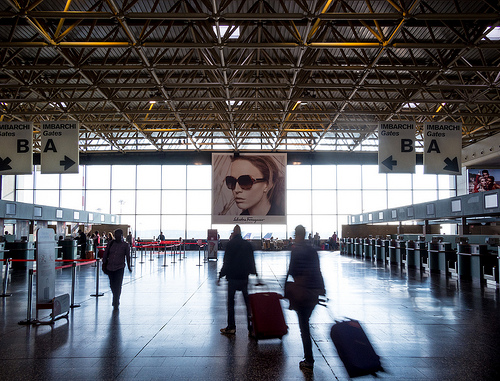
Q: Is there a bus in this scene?
A: No, there are no buses.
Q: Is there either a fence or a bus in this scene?
A: No, there are no buses or fences.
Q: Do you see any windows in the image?
A: Yes, there are windows.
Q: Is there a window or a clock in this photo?
A: Yes, there are windows.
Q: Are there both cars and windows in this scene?
A: No, there are windows but no cars.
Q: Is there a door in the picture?
A: No, there are no doors.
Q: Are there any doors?
A: No, there are no doors.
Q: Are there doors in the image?
A: No, there are no doors.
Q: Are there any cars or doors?
A: No, there are no doors or cars.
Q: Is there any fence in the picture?
A: No, there are no fences.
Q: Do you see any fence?
A: No, there are no fences.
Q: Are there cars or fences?
A: No, there are no fences or cars.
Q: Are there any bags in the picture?
A: Yes, there is a bag.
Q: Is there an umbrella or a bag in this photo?
A: Yes, there is a bag.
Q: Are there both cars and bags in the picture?
A: No, there is a bag but no cars.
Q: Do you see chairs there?
A: No, there are no chairs.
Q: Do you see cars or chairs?
A: No, there are no chairs or cars.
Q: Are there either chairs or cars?
A: No, there are no chairs or cars.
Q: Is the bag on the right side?
A: Yes, the bag is on the right of the image.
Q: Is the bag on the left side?
A: No, the bag is on the right of the image.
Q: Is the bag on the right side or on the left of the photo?
A: The bag is on the right of the image.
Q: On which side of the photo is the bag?
A: The bag is on the right of the image.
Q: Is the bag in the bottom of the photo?
A: Yes, the bag is in the bottom of the image.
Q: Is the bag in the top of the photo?
A: No, the bag is in the bottom of the image.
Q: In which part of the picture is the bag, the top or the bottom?
A: The bag is in the bottom of the image.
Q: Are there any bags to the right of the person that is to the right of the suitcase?
A: Yes, there is a bag to the right of the person.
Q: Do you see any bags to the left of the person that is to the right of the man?
A: No, the bag is to the right of the person.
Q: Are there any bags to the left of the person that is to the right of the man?
A: No, the bag is to the right of the person.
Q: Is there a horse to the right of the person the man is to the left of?
A: No, there is a bag to the right of the person.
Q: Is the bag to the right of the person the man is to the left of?
A: Yes, the bag is to the right of the person.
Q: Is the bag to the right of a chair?
A: No, the bag is to the right of the person.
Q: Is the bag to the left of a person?
A: No, the bag is to the right of a person.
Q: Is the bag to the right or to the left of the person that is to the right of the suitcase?
A: The bag is to the right of the person.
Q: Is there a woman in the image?
A: Yes, there is a woman.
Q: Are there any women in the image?
A: Yes, there is a woman.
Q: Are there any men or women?
A: Yes, there is a woman.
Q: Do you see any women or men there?
A: Yes, there is a woman.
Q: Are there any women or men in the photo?
A: Yes, there is a woman.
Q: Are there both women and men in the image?
A: Yes, there are both a woman and a man.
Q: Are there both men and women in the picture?
A: Yes, there are both a woman and a man.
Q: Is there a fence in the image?
A: No, there are no fences.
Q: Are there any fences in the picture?
A: No, there are no fences.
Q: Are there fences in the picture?
A: No, there are no fences.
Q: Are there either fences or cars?
A: No, there are no fences or cars.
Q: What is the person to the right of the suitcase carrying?
A: The person is carrying a bag.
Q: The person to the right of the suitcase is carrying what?
A: The person is carrying a bag.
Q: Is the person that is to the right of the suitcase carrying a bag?
A: Yes, the person is carrying a bag.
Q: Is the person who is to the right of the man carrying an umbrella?
A: No, the person is carrying a bag.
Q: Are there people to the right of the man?
A: Yes, there is a person to the right of the man.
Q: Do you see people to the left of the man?
A: No, the person is to the right of the man.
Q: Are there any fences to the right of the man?
A: No, there is a person to the right of the man.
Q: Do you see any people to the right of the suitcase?
A: Yes, there is a person to the right of the suitcase.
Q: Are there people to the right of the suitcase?
A: Yes, there is a person to the right of the suitcase.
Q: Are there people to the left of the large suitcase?
A: No, the person is to the right of the suitcase.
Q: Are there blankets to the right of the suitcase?
A: No, there is a person to the right of the suitcase.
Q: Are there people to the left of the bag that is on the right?
A: Yes, there is a person to the left of the bag.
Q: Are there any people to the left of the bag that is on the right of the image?
A: Yes, there is a person to the left of the bag.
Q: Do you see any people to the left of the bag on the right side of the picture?
A: Yes, there is a person to the left of the bag.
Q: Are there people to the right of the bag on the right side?
A: No, the person is to the left of the bag.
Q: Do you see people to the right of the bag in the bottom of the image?
A: No, the person is to the left of the bag.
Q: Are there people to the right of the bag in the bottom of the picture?
A: No, the person is to the left of the bag.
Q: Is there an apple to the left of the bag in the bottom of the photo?
A: No, there is a person to the left of the bag.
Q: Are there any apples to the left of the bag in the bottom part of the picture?
A: No, there is a person to the left of the bag.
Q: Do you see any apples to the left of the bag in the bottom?
A: No, there is a person to the left of the bag.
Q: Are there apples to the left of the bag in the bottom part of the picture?
A: No, there is a person to the left of the bag.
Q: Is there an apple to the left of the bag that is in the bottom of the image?
A: No, there is a person to the left of the bag.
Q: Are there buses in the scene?
A: No, there are no buses.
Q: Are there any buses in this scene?
A: No, there are no buses.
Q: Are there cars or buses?
A: No, there are no buses or cars.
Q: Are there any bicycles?
A: No, there are no bicycles.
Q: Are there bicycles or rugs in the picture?
A: No, there are no bicycles or rugs.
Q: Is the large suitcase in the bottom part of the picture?
A: Yes, the suitcase is in the bottom of the image.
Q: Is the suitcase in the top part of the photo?
A: No, the suitcase is in the bottom of the image.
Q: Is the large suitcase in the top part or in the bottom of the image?
A: The suitcase is in the bottom of the image.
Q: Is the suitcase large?
A: Yes, the suitcase is large.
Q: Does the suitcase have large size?
A: Yes, the suitcase is large.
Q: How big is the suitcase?
A: The suitcase is large.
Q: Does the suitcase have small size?
A: No, the suitcase is large.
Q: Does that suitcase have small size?
A: No, the suitcase is large.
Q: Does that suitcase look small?
A: No, the suitcase is large.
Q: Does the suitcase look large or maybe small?
A: The suitcase is large.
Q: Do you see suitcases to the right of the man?
A: Yes, there is a suitcase to the right of the man.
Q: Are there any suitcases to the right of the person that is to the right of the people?
A: Yes, there is a suitcase to the right of the man.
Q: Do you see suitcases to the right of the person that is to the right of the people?
A: Yes, there is a suitcase to the right of the man.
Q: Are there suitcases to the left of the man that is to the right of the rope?
A: No, the suitcase is to the right of the man.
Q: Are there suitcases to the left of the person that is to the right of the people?
A: No, the suitcase is to the right of the man.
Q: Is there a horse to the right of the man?
A: No, there is a suitcase to the right of the man.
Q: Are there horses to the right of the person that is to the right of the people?
A: No, there is a suitcase to the right of the man.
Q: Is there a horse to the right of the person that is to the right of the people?
A: No, there is a suitcase to the right of the man.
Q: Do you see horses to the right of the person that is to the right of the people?
A: No, there is a suitcase to the right of the man.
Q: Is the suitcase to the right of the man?
A: Yes, the suitcase is to the right of the man.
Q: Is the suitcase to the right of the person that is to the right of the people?
A: Yes, the suitcase is to the right of the man.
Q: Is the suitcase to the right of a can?
A: No, the suitcase is to the right of the man.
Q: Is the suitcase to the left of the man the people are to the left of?
A: No, the suitcase is to the right of the man.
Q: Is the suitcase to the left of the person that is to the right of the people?
A: No, the suitcase is to the right of the man.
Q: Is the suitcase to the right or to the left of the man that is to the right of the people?
A: The suitcase is to the right of the man.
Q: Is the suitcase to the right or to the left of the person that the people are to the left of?
A: The suitcase is to the right of the man.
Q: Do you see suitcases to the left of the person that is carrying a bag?
A: Yes, there is a suitcase to the left of the person.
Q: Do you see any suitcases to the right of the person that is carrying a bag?
A: No, the suitcase is to the left of the person.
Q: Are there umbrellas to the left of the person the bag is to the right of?
A: No, there is a suitcase to the left of the person.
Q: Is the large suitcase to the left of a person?
A: Yes, the suitcase is to the left of a person.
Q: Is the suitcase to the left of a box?
A: No, the suitcase is to the left of a person.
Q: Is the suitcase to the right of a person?
A: No, the suitcase is to the left of a person.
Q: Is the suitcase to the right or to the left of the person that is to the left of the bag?
A: The suitcase is to the left of the person.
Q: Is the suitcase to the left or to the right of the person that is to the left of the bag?
A: The suitcase is to the left of the person.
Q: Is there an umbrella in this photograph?
A: No, there are no umbrellas.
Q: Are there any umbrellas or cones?
A: No, there are no umbrellas or cones.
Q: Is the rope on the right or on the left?
A: The rope is on the left of the image.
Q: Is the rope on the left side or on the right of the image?
A: The rope is on the left of the image.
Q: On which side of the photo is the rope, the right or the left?
A: The rope is on the left of the image.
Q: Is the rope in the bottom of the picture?
A: Yes, the rope is in the bottom of the image.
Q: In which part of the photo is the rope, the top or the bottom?
A: The rope is in the bottom of the image.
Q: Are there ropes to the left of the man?
A: Yes, there is a rope to the left of the man.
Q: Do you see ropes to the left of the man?
A: Yes, there is a rope to the left of the man.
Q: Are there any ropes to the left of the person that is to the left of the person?
A: Yes, there is a rope to the left of the man.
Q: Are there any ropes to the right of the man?
A: No, the rope is to the left of the man.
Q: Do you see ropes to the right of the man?
A: No, the rope is to the left of the man.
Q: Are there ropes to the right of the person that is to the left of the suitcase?
A: No, the rope is to the left of the man.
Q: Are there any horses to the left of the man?
A: No, there is a rope to the left of the man.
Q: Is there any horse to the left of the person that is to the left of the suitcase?
A: No, there is a rope to the left of the man.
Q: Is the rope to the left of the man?
A: Yes, the rope is to the left of the man.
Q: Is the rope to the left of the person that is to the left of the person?
A: Yes, the rope is to the left of the man.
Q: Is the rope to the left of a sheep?
A: No, the rope is to the left of the man.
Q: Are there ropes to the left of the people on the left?
A: Yes, there is a rope to the left of the people.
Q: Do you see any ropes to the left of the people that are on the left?
A: Yes, there is a rope to the left of the people.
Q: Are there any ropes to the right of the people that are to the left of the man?
A: No, the rope is to the left of the people.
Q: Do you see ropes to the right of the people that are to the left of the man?
A: No, the rope is to the left of the people.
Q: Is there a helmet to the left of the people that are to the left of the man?
A: No, there is a rope to the left of the people.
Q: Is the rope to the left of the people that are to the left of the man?
A: Yes, the rope is to the left of the people.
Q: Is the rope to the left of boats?
A: No, the rope is to the left of the people.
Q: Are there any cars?
A: No, there are no cars.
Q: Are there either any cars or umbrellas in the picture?
A: No, there are no cars or umbrellas.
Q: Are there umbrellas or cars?
A: No, there are no cars or umbrellas.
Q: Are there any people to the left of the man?
A: Yes, there are people to the left of the man.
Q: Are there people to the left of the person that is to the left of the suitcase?
A: Yes, there are people to the left of the man.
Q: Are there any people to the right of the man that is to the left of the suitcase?
A: No, the people are to the left of the man.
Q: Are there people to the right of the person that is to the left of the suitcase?
A: No, the people are to the left of the man.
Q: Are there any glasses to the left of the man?
A: No, there are people to the left of the man.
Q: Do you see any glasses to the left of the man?
A: No, there are people to the left of the man.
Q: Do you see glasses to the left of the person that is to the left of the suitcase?
A: No, there are people to the left of the man.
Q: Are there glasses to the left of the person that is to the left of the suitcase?
A: No, there are people to the left of the man.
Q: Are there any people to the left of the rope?
A: No, the people are to the right of the rope.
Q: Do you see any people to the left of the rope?
A: No, the people are to the right of the rope.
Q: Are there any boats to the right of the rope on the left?
A: No, there are people to the right of the rope.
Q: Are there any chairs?
A: No, there are no chairs.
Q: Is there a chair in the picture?
A: No, there are no chairs.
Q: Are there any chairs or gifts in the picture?
A: No, there are no chairs or gifts.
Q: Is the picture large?
A: Yes, the picture is large.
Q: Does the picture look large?
A: Yes, the picture is large.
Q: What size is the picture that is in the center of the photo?
A: The picture is large.